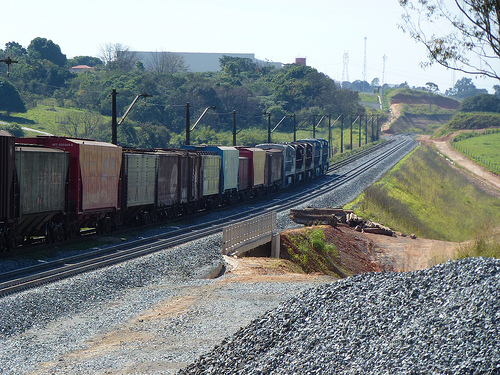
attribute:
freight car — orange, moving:
[18, 138, 117, 232]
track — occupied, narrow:
[2, 134, 394, 259]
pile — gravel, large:
[180, 254, 499, 375]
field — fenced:
[455, 132, 500, 173]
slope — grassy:
[344, 143, 498, 258]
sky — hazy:
[2, 1, 499, 94]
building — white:
[71, 64, 93, 76]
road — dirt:
[432, 141, 498, 190]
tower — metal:
[361, 35, 367, 87]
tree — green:
[398, 1, 499, 80]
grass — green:
[285, 227, 336, 264]